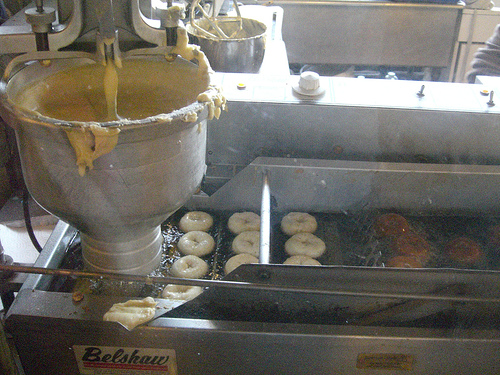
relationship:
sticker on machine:
[353, 346, 418, 373] [0, 32, 497, 374]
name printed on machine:
[74, 335, 178, 373] [0, 32, 497, 374]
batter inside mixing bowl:
[41, 73, 181, 115] [9, 44, 226, 298]